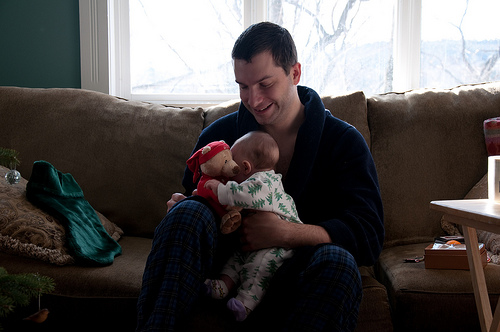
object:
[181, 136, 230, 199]
pajamas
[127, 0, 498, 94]
window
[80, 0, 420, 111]
frame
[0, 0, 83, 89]
wall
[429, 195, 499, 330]
tray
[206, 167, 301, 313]
pajamas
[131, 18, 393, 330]
man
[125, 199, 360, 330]
pants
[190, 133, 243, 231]
bear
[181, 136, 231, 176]
hat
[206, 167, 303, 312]
pjs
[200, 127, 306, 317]
baby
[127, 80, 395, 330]
robe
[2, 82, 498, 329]
couch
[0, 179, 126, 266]
pillow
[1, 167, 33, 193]
ball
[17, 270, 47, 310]
ornament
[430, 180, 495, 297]
table